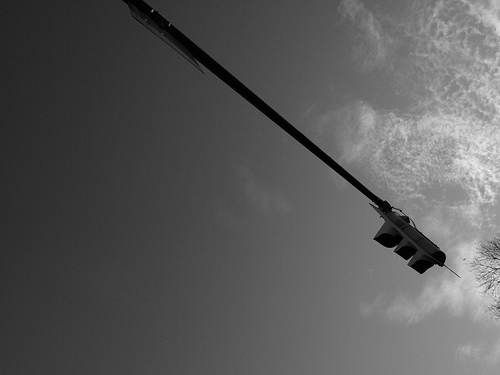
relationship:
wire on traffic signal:
[391, 205, 419, 230] [369, 202, 447, 277]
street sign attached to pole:
[128, 2, 204, 73] [123, 0, 394, 213]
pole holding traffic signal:
[123, 0, 394, 213] [369, 202, 447, 277]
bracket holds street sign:
[145, 7, 156, 20] [128, 2, 204, 73]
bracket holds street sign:
[163, 20, 173, 35] [128, 2, 204, 73]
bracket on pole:
[145, 7, 156, 20] [123, 0, 394, 213]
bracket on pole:
[163, 20, 173, 35] [123, 0, 394, 213]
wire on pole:
[391, 205, 419, 230] [123, 0, 394, 213]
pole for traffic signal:
[123, 0, 394, 213] [369, 202, 447, 277]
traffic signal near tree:
[369, 202, 447, 277] [465, 235, 499, 320]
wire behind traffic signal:
[391, 205, 419, 230] [369, 202, 447, 277]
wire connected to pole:
[391, 205, 419, 230] [123, 0, 394, 213]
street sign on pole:
[128, 2, 204, 73] [123, 0, 394, 213]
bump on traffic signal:
[386, 212, 446, 264] [369, 202, 447, 277]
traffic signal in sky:
[369, 202, 447, 277] [1, 0, 498, 375]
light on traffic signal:
[375, 233, 397, 247] [369, 202, 447, 277]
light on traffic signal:
[395, 243, 413, 259] [369, 202, 447, 277]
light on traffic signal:
[412, 261, 432, 273] [369, 202, 447, 277]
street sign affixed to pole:
[128, 2, 204, 73] [123, 0, 394, 213]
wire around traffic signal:
[391, 205, 419, 230] [369, 202, 447, 277]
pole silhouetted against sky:
[123, 0, 394, 213] [1, 0, 498, 375]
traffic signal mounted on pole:
[369, 202, 447, 277] [123, 0, 394, 213]